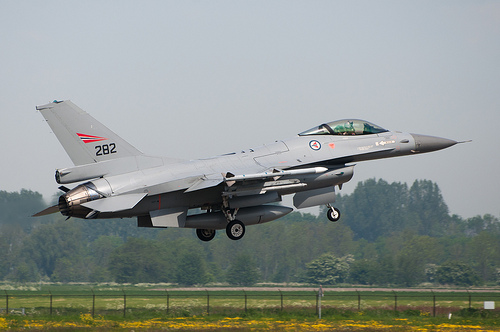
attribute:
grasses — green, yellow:
[1, 280, 497, 328]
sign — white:
[462, 275, 489, 315]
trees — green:
[36, 191, 481, 314]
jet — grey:
[26, 104, 477, 281]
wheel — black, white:
[317, 190, 379, 263]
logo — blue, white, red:
[288, 139, 326, 157]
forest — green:
[353, 194, 437, 274]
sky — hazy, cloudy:
[134, 67, 231, 107]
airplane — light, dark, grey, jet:
[38, 97, 440, 217]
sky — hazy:
[136, 42, 289, 95]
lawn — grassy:
[79, 266, 259, 330]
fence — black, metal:
[80, 276, 297, 328]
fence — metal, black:
[103, 277, 271, 325]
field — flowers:
[79, 310, 199, 321]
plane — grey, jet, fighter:
[74, 104, 364, 233]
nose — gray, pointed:
[407, 134, 457, 154]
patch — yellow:
[126, 316, 173, 328]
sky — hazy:
[2, 2, 498, 226]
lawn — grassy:
[3, 273, 498, 331]